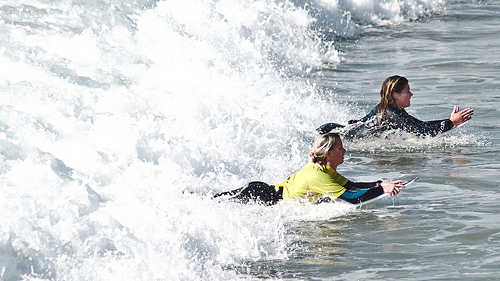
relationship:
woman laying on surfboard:
[208, 133, 408, 207] [312, 176, 418, 221]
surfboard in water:
[312, 176, 418, 221] [0, 5, 499, 279]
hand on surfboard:
[379, 180, 406, 197] [312, 176, 418, 221]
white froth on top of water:
[2, 3, 495, 280] [0, 5, 499, 279]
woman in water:
[208, 133, 408, 207] [0, 5, 499, 279]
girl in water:
[316, 74, 475, 142] [0, 5, 499, 279]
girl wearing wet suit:
[316, 74, 475, 142] [317, 98, 455, 142]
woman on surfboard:
[208, 133, 408, 207] [343, 174, 421, 210]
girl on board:
[316, 74, 475, 142] [422, 119, 474, 140]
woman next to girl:
[208, 133, 408, 207] [316, 74, 475, 142]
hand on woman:
[379, 180, 406, 197] [208, 133, 408, 207]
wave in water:
[3, 3, 448, 280] [0, 5, 499, 279]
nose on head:
[342, 148, 347, 155] [307, 133, 347, 169]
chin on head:
[337, 157, 345, 165] [307, 133, 347, 169]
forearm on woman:
[355, 187, 382, 205] [208, 133, 408, 207]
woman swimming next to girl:
[208, 133, 408, 207] [316, 74, 475, 142]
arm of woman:
[309, 169, 409, 205] [208, 133, 408, 207]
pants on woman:
[212, 180, 284, 206] [208, 133, 408, 207]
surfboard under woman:
[312, 176, 418, 221] [208, 133, 408, 207]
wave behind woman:
[3, 3, 448, 280] [208, 133, 408, 207]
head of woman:
[381, 76, 414, 109] [318, 77, 474, 141]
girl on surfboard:
[316, 74, 475, 142] [312, 176, 418, 221]